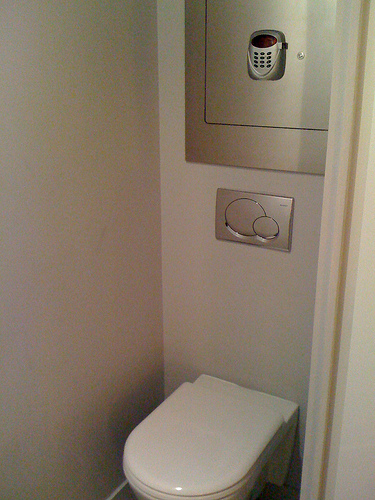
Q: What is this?
A: Toilet.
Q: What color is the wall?
A: White.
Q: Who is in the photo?
A: No one.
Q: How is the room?
A: Clean.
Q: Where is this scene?
A: In a bathroom.